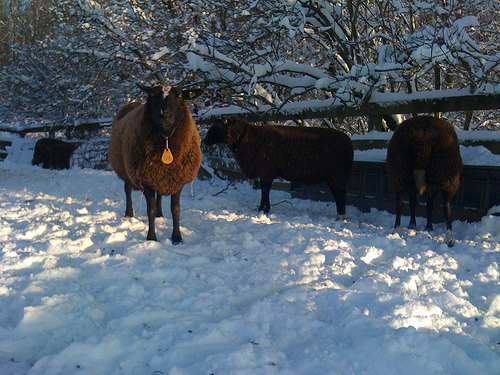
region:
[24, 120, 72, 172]
black and brown sheep in white snow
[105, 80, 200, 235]
black and brown sheep in white snow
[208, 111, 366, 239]
black and brown sheep in white snow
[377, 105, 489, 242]
black and brown sheep in white snow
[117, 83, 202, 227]
black and brown sheep standing in white snow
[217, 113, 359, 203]
black and brown sheep standing in white snow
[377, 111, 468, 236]
black and brown sheep standing in white snow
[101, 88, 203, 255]
black and brown sheep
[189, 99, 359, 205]
black and brown sheep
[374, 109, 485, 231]
black and brown sheep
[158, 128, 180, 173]
Orange tag on sheep's collar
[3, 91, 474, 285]
Sheep in a snow covered field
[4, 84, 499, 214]
Wooden fence covered in snow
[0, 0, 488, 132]
Tree with no leaves covered in snow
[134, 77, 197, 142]
Dark head of brown sheep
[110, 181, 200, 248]
Sheep's legs standing in snow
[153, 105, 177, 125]
Black nose of sheep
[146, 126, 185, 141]
Collar of sheep around it's neck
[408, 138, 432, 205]
Tail of sheep drooping down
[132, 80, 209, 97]
Two ears on sheep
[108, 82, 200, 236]
brown and black sheep standing in white snow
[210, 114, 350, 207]
brown and black sheep standing in white snow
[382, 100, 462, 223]
brown and black sheep standing in white snow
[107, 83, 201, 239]
brown and black sheep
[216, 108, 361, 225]
brown and black sheep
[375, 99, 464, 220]
brown and black sheep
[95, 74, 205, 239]
brown and black sheep standing in snow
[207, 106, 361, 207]
brown and black sheep standing in snow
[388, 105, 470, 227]
brown and black sheep standing in snow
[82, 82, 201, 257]
brown sheep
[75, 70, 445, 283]
three sheep in the snow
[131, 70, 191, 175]
the sheep is looking at the camera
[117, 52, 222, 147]
the sheep head is black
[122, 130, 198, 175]
sheep is wearing a tag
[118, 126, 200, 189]
the tag is yellow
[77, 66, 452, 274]
the sheep are brown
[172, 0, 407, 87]
the snow is on the trees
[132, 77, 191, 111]
the eyes are open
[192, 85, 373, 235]
the sheep is facing to the left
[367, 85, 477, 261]
the backside of a sheep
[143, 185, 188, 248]
the front legs of the reindeer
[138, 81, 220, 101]
the reindeer's antlers in the picture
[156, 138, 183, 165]
the tag on the reindeer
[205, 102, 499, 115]
the railing of the fence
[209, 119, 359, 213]
the middle reindeer in the picture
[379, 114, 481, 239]
the reindeer on the right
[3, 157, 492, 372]
the snow that was on the ground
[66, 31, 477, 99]
the trees covered with snow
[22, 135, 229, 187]
the wall by the fence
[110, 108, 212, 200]
the brown body of the reindeer